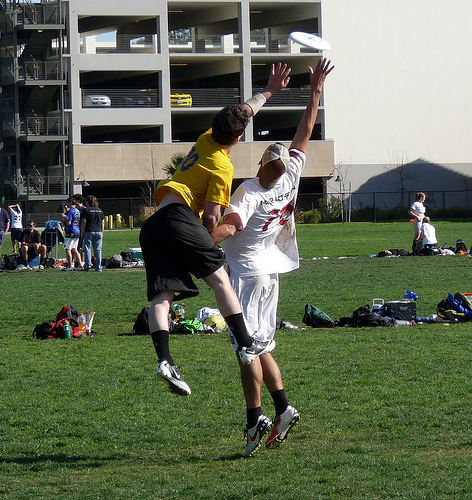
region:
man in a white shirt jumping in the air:
[223, 57, 342, 452]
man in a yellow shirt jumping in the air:
[138, 64, 295, 393]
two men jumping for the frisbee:
[139, 65, 335, 456]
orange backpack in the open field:
[32, 302, 95, 341]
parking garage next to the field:
[1, 0, 336, 225]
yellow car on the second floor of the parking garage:
[164, 90, 192, 106]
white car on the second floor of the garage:
[79, 90, 111, 106]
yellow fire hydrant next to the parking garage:
[112, 213, 124, 228]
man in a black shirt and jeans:
[79, 195, 105, 271]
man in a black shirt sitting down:
[15, 220, 48, 269]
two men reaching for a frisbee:
[137, 27, 338, 454]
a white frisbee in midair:
[284, 25, 339, 62]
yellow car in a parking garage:
[163, 84, 203, 109]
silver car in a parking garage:
[80, 85, 119, 107]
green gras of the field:
[347, 385, 440, 465]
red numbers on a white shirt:
[261, 207, 303, 236]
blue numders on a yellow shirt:
[177, 145, 209, 176]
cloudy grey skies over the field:
[357, 29, 456, 138]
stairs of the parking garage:
[1, 24, 73, 197]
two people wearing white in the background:
[399, 181, 445, 270]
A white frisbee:
[286, 28, 332, 52]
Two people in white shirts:
[410, 188, 441, 257]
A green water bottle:
[58, 316, 72, 340]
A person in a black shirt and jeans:
[83, 195, 104, 271]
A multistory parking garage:
[2, 1, 327, 224]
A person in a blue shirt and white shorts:
[63, 195, 82, 270]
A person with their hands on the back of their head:
[7, 201, 25, 254]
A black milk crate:
[382, 298, 416, 323]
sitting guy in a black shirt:
[22, 220, 48, 269]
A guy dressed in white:
[228, 52, 322, 456]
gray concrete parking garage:
[36, 1, 331, 224]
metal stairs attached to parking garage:
[0, 0, 66, 198]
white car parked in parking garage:
[81, 89, 107, 103]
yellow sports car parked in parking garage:
[167, 85, 191, 102]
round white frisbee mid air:
[287, 25, 327, 42]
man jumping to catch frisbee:
[136, 59, 289, 395]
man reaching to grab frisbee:
[210, 51, 329, 456]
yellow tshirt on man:
[152, 124, 229, 206]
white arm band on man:
[243, 91, 263, 113]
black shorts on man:
[139, 202, 224, 296]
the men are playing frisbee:
[134, 35, 374, 440]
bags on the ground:
[302, 275, 462, 350]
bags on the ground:
[299, 296, 352, 335]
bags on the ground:
[26, 302, 100, 349]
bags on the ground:
[354, 226, 428, 262]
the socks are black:
[136, 305, 293, 425]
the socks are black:
[231, 381, 308, 418]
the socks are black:
[125, 305, 253, 385]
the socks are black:
[248, 393, 327, 433]